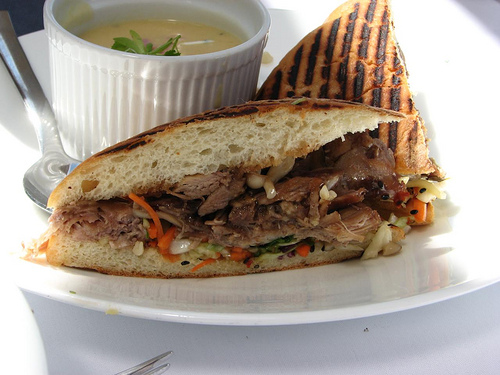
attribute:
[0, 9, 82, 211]
spoon — silver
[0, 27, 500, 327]
plate — white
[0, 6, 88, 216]
spoon — silver, long, metal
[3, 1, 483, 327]
plate — round, white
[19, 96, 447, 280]
sandwich — meat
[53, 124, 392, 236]
stuffing — beef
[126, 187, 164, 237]
slice — carrot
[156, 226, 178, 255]
slice — carrot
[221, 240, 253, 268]
slice — carrot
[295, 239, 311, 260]
slice — carrot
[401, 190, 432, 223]
slice — carrot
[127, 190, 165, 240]
piece — carrot, julienne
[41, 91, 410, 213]
piece — toasted, bread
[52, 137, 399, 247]
meat — cooked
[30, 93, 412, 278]
sandwich — uneaten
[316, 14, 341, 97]
line — toasted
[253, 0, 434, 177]
bread — sandwich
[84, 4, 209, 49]
soup — yellow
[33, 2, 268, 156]
ramekin — white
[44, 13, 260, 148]
bowl — small, round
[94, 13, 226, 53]
soup — some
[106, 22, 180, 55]
leaf — green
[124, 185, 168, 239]
slice — carrot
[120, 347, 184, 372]
tines — fork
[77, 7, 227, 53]
soup — orange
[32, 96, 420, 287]
half — sandwich, small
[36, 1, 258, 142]
bowl — small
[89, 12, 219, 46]
soup — creamy, onion